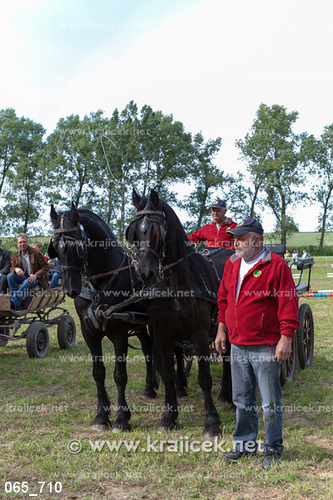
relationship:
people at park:
[0, 75, 309, 415] [22, 28, 235, 363]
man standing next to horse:
[212, 215, 299, 464] [122, 185, 227, 429]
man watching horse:
[5, 231, 51, 308] [46, 201, 147, 433]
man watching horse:
[5, 231, 51, 308] [122, 185, 227, 429]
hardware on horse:
[79, 288, 150, 332] [122, 185, 233, 442]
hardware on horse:
[79, 288, 150, 332] [46, 201, 147, 433]